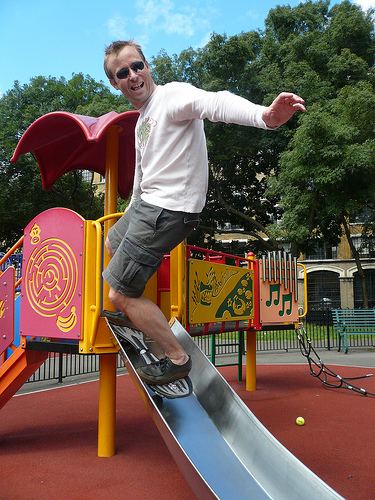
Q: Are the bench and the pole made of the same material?
A: Yes, both the bench and the pole are made of metal.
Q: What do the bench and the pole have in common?
A: The material, both the bench and the pole are metallic.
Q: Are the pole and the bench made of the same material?
A: Yes, both the pole and the bench are made of metal.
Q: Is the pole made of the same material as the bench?
A: Yes, both the pole and the bench are made of metal.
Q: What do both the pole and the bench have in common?
A: The material, both the pole and the bench are metallic.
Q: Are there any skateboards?
A: Yes, there is a skateboard.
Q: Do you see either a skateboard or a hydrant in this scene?
A: Yes, there is a skateboard.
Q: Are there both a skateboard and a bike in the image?
A: No, there is a skateboard but no bikes.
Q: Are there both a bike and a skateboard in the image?
A: No, there is a skateboard but no bikes.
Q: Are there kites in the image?
A: No, there are no kites.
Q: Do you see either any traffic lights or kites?
A: No, there are no kites or traffic lights.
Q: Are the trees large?
A: Yes, the trees are large.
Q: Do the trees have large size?
A: Yes, the trees are large.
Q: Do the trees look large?
A: Yes, the trees are large.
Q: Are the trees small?
A: No, the trees are large.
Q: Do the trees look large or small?
A: The trees are large.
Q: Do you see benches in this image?
A: Yes, there is a bench.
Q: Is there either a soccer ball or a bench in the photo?
A: Yes, there is a bench.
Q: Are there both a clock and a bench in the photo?
A: No, there is a bench but no clocks.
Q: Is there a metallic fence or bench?
A: Yes, there is a metal bench.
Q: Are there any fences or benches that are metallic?
A: Yes, the bench is metallic.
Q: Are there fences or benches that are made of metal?
A: Yes, the bench is made of metal.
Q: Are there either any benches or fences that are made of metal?
A: Yes, the bench is made of metal.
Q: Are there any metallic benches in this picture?
A: Yes, there is a metal bench.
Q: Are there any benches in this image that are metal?
A: Yes, there is a metal bench.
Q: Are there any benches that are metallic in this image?
A: Yes, there is a metal bench.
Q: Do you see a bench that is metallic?
A: Yes, there is a bench that is metallic.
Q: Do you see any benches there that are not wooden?
A: Yes, there is a metallic bench.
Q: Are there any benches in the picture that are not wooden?
A: Yes, there is a metallic bench.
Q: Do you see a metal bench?
A: Yes, there is a bench that is made of metal.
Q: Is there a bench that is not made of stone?
A: Yes, there is a bench that is made of metal.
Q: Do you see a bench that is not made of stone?
A: Yes, there is a bench that is made of metal.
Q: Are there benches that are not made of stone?
A: Yes, there is a bench that is made of metal.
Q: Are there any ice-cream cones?
A: No, there are no ice-cream cones.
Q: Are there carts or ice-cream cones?
A: No, there are no ice-cream cones or carts.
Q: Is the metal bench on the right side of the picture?
A: Yes, the bench is on the right of the image.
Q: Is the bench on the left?
A: No, the bench is on the right of the image.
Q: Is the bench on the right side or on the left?
A: The bench is on the right of the image.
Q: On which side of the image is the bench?
A: The bench is on the right of the image.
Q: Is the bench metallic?
A: Yes, the bench is metallic.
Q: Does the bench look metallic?
A: Yes, the bench is metallic.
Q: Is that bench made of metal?
A: Yes, the bench is made of metal.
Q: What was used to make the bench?
A: The bench is made of metal.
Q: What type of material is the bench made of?
A: The bench is made of metal.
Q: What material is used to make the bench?
A: The bench is made of metal.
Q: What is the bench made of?
A: The bench is made of metal.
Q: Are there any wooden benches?
A: No, there is a bench but it is metallic.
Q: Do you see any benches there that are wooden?
A: No, there is a bench but it is metallic.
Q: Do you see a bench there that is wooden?
A: No, there is a bench but it is metallic.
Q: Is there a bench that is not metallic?
A: No, there is a bench but it is metallic.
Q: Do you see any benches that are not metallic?
A: No, there is a bench but it is metallic.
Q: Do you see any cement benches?
A: No, there is a bench but it is made of metal.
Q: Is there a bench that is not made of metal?
A: No, there is a bench but it is made of metal.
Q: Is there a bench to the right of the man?
A: Yes, there is a bench to the right of the man.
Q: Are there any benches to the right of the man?
A: Yes, there is a bench to the right of the man.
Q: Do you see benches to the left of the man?
A: No, the bench is to the right of the man.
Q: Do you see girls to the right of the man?
A: No, there is a bench to the right of the man.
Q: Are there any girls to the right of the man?
A: No, there is a bench to the right of the man.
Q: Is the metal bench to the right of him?
A: Yes, the bench is to the right of the man.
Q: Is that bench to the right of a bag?
A: No, the bench is to the right of the man.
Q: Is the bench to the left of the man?
A: No, the bench is to the right of the man.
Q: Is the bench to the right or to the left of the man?
A: The bench is to the right of the man.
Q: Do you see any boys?
A: No, there are no boys.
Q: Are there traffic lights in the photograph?
A: No, there are no traffic lights.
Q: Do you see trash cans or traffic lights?
A: No, there are no traffic lights or trash cans.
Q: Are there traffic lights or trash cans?
A: No, there are no traffic lights or trash cans.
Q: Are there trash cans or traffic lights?
A: No, there are no traffic lights or trash cans.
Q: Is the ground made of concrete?
A: No, the ground is made of rubber.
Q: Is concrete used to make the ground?
A: No, the ground is made of rubber.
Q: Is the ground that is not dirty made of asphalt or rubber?
A: The ground is made of rubber.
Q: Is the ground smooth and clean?
A: Yes, the ground is smooth and clean.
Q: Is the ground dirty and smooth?
A: No, the ground is smooth but clean.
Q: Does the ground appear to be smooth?
A: Yes, the ground is smooth.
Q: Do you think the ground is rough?
A: No, the ground is smooth.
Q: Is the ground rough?
A: No, the ground is smooth.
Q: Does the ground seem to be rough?
A: No, the ground is smooth.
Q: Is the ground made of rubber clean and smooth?
A: Yes, the ground is clean and smooth.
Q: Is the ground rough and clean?
A: No, the ground is clean but smooth.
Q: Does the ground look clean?
A: Yes, the ground is clean.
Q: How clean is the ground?
A: The ground is clean.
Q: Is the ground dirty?
A: No, the ground is clean.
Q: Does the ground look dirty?
A: No, the ground is clean.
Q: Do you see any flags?
A: No, there are no flags.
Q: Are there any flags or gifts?
A: No, there are no flags or gifts.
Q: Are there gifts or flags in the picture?
A: No, there are no flags or gifts.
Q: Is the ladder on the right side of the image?
A: Yes, the ladder is on the right of the image.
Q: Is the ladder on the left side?
A: No, the ladder is on the right of the image.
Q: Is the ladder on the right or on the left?
A: The ladder is on the right of the image.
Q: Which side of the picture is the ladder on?
A: The ladder is on the right of the image.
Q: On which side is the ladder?
A: The ladder is on the right of the image.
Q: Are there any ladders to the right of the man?
A: Yes, there is a ladder to the right of the man.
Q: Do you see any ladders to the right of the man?
A: Yes, there is a ladder to the right of the man.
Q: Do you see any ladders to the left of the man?
A: No, the ladder is to the right of the man.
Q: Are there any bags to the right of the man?
A: No, there is a ladder to the right of the man.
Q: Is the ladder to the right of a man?
A: Yes, the ladder is to the right of a man.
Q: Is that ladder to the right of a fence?
A: No, the ladder is to the right of a man.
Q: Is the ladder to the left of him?
A: No, the ladder is to the right of a man.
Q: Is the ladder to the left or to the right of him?
A: The ladder is to the right of the man.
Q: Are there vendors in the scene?
A: No, there are no vendors.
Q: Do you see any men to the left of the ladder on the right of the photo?
A: Yes, there is a man to the left of the ladder.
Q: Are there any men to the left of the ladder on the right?
A: Yes, there is a man to the left of the ladder.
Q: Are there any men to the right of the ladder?
A: No, the man is to the left of the ladder.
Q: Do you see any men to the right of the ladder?
A: No, the man is to the left of the ladder.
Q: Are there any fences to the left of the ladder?
A: No, there is a man to the left of the ladder.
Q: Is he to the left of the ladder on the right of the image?
A: Yes, the man is to the left of the ladder.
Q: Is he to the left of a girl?
A: No, the man is to the left of the ladder.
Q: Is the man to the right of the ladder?
A: No, the man is to the left of the ladder.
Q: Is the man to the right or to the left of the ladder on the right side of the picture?
A: The man is to the left of the ladder.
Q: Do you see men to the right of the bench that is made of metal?
A: No, the man is to the left of the bench.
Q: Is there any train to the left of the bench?
A: No, there is a man to the left of the bench.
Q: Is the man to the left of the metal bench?
A: Yes, the man is to the left of the bench.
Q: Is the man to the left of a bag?
A: No, the man is to the left of the bench.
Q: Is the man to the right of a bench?
A: No, the man is to the left of a bench.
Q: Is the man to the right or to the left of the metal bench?
A: The man is to the left of the bench.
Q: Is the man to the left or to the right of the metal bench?
A: The man is to the left of the bench.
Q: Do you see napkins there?
A: No, there are no napkins.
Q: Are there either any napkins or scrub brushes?
A: No, there are no napkins or scrub brushes.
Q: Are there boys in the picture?
A: No, there are no boys.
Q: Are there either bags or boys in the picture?
A: No, there are no boys or bags.